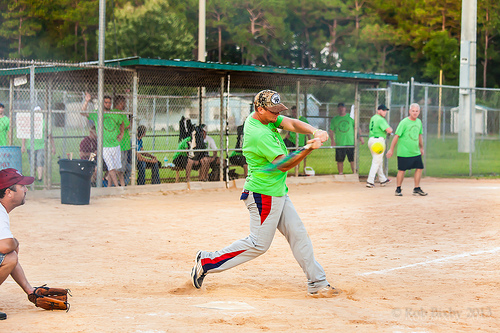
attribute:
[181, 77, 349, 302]
pants — gray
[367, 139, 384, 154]
softball — yellow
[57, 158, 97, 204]
trash can — blue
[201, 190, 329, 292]
pants — gray, red, black, grey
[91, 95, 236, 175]
team — green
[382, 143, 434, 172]
shorts — black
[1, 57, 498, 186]
fence — metal, chain link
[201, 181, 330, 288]
pants — long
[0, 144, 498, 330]
field — Baseball field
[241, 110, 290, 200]
shirt — green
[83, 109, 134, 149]
shirt — green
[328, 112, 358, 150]
shirt — green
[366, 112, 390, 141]
shirt — green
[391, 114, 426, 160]
shirt — green